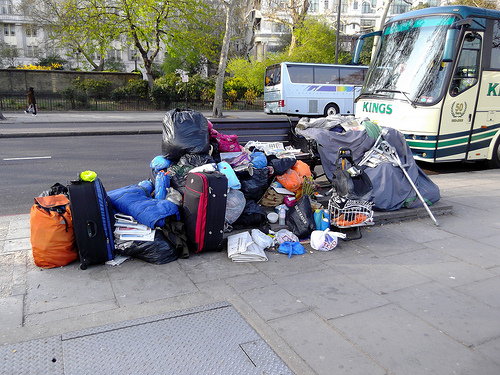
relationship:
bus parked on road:
[265, 62, 369, 119] [0, 110, 363, 216]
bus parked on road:
[356, 3, 498, 168] [0, 110, 363, 216]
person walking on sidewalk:
[25, 85, 38, 117] [2, 108, 299, 125]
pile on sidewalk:
[29, 110, 436, 264] [0, 168, 499, 373]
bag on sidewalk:
[29, 193, 78, 270] [0, 168, 499, 373]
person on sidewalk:
[25, 85, 38, 117] [2, 108, 299, 125]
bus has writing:
[356, 3, 498, 168] [362, 102, 393, 116]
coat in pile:
[106, 185, 182, 230] [29, 110, 436, 264]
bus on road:
[265, 62, 369, 119] [0, 110, 363, 216]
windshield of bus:
[360, 15, 461, 104] [356, 3, 498, 168]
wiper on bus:
[376, 89, 419, 109] [356, 3, 498, 168]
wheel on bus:
[324, 103, 341, 119] [265, 62, 369, 119]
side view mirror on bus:
[441, 27, 459, 63] [356, 3, 498, 168]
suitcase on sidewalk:
[183, 169, 230, 255] [0, 168, 499, 373]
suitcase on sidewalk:
[68, 174, 117, 276] [0, 168, 499, 373]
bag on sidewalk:
[309, 227, 347, 254] [0, 168, 499, 373]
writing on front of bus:
[362, 102, 393, 116] [356, 3, 498, 168]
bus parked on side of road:
[265, 62, 369, 119] [0, 110, 363, 216]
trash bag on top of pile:
[158, 108, 212, 162] [29, 110, 436, 264]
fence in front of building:
[0, 93, 265, 114] [0, 1, 210, 83]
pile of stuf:
[29, 110, 436, 264] [27, 170, 126, 266]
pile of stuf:
[29, 110, 436, 264] [153, 113, 287, 256]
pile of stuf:
[29, 110, 436, 264] [106, 173, 185, 270]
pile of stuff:
[29, 110, 436, 264] [293, 118, 442, 225]